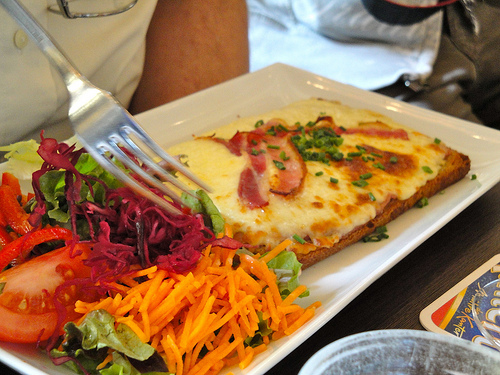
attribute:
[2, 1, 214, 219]
fork — four-pronged, silver 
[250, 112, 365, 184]
chives — chopped 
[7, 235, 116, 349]
tomato — red, ripe , juicy 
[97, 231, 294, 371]
carrots — Bright , orange , julienned 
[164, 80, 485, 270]
pizza — cheesy , Bacon 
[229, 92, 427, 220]
chives — chopped 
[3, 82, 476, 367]
lunch — healthy 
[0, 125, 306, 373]
salad — fresh , colorful 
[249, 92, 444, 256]
chives — chopped 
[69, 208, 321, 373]
carrots — portion , shredded 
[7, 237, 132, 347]
tomato — red, slice 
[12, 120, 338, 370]
cabbage — red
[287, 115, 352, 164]
chives — spoonful 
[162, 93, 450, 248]
cheese — Melted